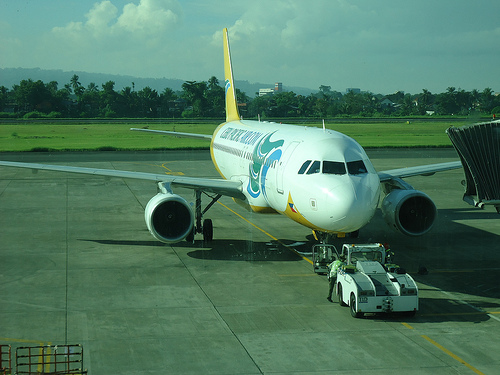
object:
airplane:
[0, 25, 463, 246]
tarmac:
[1, 148, 499, 374]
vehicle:
[311, 242, 420, 318]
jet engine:
[143, 192, 195, 243]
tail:
[221, 27, 242, 121]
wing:
[0, 158, 244, 201]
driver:
[325, 255, 345, 303]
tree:
[401, 93, 418, 116]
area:
[0, 122, 474, 153]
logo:
[246, 129, 284, 199]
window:
[321, 160, 346, 176]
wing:
[376, 161, 465, 182]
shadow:
[360, 297, 499, 324]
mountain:
[0, 66, 321, 97]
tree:
[70, 74, 81, 90]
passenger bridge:
[444, 118, 500, 208]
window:
[346, 159, 369, 175]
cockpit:
[298, 160, 313, 176]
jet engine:
[380, 187, 438, 237]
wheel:
[201, 218, 213, 243]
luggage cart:
[0, 342, 89, 375]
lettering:
[250, 131, 262, 146]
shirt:
[327, 260, 345, 279]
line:
[161, 160, 314, 265]